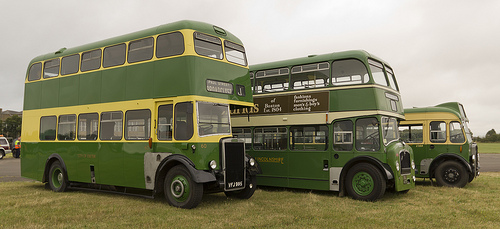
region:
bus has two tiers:
[23, 45, 235, 197]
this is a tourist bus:
[245, 59, 415, 202]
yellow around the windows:
[16, 101, 218, 142]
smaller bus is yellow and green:
[410, 107, 475, 186]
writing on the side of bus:
[256, 85, 340, 116]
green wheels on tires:
[353, 172, 374, 202]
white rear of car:
[0, 128, 15, 153]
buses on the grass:
[58, 30, 496, 227]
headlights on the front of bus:
[204, 159, 265, 172]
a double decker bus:
[4, 20, 272, 217]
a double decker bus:
[18, 30, 273, 215]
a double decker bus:
[0, 12, 267, 216]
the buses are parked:
[16, 2, 496, 222]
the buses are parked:
[5, 20, 479, 218]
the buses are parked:
[4, 14, 487, 219]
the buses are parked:
[11, 31, 493, 223]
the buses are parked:
[20, 20, 499, 227]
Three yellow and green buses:
[25, 20, 473, 192]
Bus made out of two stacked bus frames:
[265, 52, 379, 197]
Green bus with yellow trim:
[25, 25, 223, 190]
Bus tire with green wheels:
[342, 162, 379, 198]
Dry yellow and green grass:
[4, 198, 121, 225]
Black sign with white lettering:
[205, 79, 235, 94]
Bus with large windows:
[32, 101, 149, 142]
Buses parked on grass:
[10, 30, 472, 222]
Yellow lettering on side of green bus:
[247, 154, 287, 166]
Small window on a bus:
[153, 26, 185, 61]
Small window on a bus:
[122, 35, 156, 67]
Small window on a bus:
[100, 40, 126, 73]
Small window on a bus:
[76, 35, 110, 91]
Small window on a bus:
[57, 51, 86, 83]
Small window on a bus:
[44, 60, 64, 87]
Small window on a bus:
[57, 112, 74, 140]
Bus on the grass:
[7, 41, 247, 201]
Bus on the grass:
[250, 46, 410, 223]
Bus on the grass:
[404, 88, 496, 202]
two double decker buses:
[18, 21, 403, 228]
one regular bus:
[393, 95, 498, 195]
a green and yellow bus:
[15, 18, 260, 216]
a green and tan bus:
[222, 43, 444, 220]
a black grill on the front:
[216, 135, 250, 197]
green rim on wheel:
[338, 170, 378, 203]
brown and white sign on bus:
[236, 92, 346, 129]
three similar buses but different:
[16, 27, 487, 228]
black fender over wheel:
[143, 149, 245, 211]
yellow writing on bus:
[246, 147, 318, 181]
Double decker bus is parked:
[17, 22, 261, 202]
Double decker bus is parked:
[227, 53, 417, 198]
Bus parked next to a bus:
[394, 100, 479, 188]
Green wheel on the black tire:
[351, 170, 374, 195]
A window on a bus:
[153, 30, 183, 56]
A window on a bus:
[126, 35, 151, 60]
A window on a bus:
[79, 50, 103, 69]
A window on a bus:
[62, 56, 82, 76]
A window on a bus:
[44, 59, 59, 78]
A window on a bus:
[28, 61, 42, 83]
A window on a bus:
[59, 113, 76, 137]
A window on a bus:
[39, 114, 56, 136]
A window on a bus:
[79, 113, 99, 137]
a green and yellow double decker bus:
[18, 17, 263, 207]